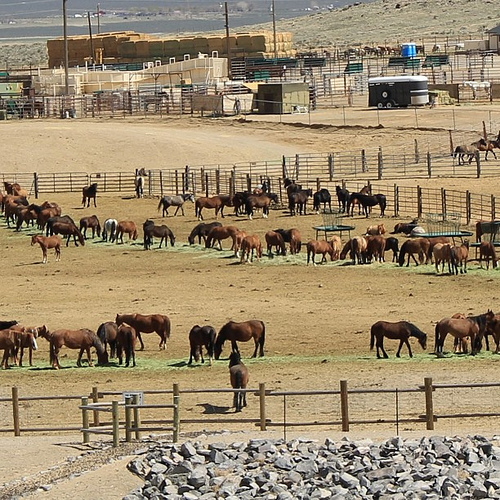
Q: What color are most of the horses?
A: Brown.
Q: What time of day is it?
A: Day time.